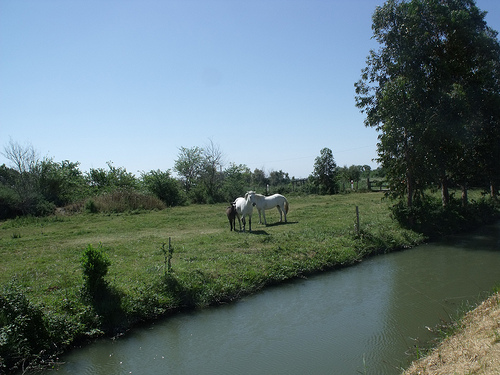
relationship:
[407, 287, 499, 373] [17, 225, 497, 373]
grass by water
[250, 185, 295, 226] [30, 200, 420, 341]
horse in field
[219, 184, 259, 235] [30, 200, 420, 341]
horse in field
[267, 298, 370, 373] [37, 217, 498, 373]
water in stream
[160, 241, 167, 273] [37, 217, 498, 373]
plant next to stream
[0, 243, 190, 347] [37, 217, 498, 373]
plant next to stream